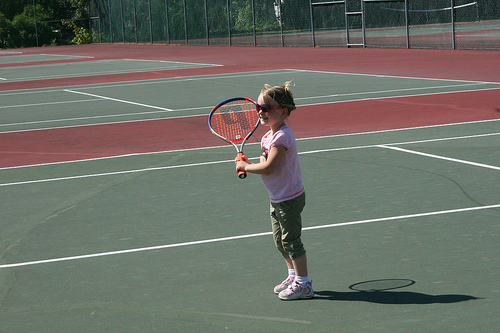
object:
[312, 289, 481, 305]
girl's shadow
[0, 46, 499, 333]
ground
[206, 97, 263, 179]
racket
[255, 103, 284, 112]
girl's sunglasses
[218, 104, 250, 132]
'p'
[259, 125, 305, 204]
pink shirt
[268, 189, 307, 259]
green pants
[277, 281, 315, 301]
shoes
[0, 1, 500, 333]
court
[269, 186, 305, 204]
edge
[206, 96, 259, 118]
top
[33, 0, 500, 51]
fence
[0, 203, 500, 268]
line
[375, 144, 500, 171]
line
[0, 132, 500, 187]
line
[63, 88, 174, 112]
line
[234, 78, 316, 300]
girl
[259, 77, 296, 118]
hair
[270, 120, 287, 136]
neck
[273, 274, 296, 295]
tennis shoe